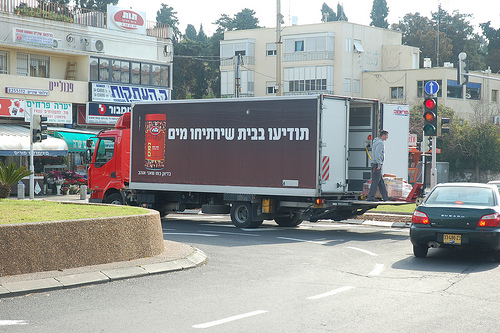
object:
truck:
[85, 94, 385, 225]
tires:
[228, 199, 258, 229]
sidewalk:
[1, 234, 209, 300]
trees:
[427, 2, 494, 69]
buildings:
[216, 20, 499, 198]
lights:
[423, 96, 440, 135]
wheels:
[271, 208, 306, 227]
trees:
[389, 13, 451, 66]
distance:
[170, 5, 496, 113]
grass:
[0, 189, 138, 225]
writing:
[165, 127, 177, 139]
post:
[430, 138, 438, 194]